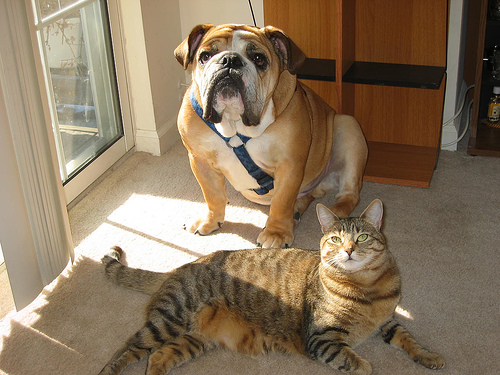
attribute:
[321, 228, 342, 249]
eye — bright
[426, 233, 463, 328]
carpet — beige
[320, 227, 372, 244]
eyes — yellow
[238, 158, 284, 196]
harness — black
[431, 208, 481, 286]
carpet — white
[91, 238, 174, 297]
tail — cat's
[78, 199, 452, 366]
cat — laying down, gray, tabby color, green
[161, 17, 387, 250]
dog — brown, white, sitting up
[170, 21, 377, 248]
dog — brown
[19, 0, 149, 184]
door — sliding glass door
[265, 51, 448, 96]
shelf — wooden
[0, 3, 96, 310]
blinds — white, vertical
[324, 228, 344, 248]
eye — green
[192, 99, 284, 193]
harness — blue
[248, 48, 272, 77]
eye — brown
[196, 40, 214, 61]
eye — brown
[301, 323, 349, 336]
stripe — black